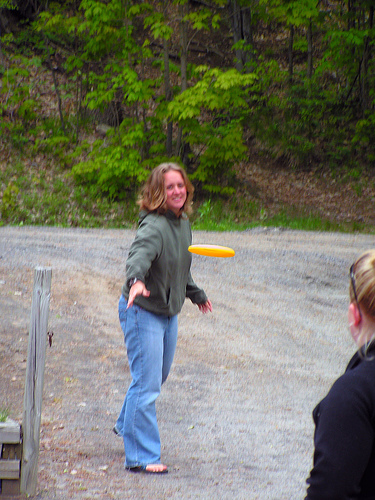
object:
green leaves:
[106, 49, 139, 85]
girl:
[112, 161, 212, 475]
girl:
[305, 249, 375, 500]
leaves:
[164, 65, 260, 177]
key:
[47, 331, 53, 347]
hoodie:
[121, 210, 208, 317]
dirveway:
[0, 228, 373, 500]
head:
[348, 249, 375, 346]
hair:
[347, 249, 374, 363]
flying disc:
[188, 244, 236, 257]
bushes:
[0, 0, 375, 230]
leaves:
[299, 18, 375, 155]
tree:
[0, 0, 375, 201]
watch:
[130, 276, 137, 287]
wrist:
[125, 275, 146, 285]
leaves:
[117, 66, 146, 108]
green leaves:
[0, 60, 45, 113]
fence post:
[17, 267, 55, 497]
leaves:
[252, 79, 287, 134]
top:
[303, 341, 375, 500]